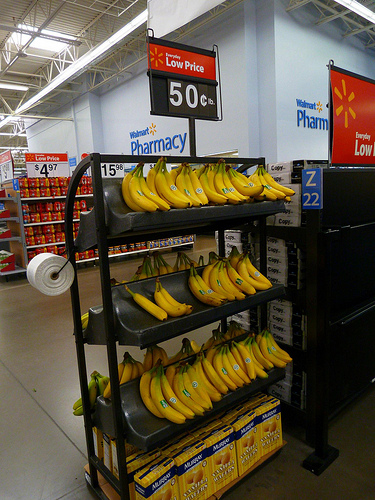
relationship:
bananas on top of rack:
[128, 165, 296, 438] [61, 146, 304, 500]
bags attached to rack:
[25, 251, 75, 296] [61, 146, 304, 500]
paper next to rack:
[214, 159, 329, 409] [61, 146, 304, 500]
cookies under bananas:
[96, 392, 285, 499] [128, 165, 296, 438]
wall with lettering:
[256, 0, 374, 162] [295, 99, 327, 131]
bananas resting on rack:
[128, 165, 296, 438] [61, 146, 304, 500]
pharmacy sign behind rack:
[128, 122, 188, 156] [61, 146, 304, 500]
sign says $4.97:
[25, 151, 70, 178] [34, 163, 58, 177]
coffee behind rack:
[17, 177, 98, 262] [61, 146, 304, 500]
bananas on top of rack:
[128, 165, 296, 438] [102, 176, 289, 451]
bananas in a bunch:
[128, 165, 296, 438] [122, 166, 171, 214]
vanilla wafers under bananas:
[91, 394, 284, 499] [128, 165, 296, 438]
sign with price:
[144, 31, 224, 123] [168, 82, 214, 109]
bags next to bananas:
[25, 251, 75, 296] [128, 165, 296, 438]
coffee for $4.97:
[17, 177, 98, 262] [34, 163, 58, 177]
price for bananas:
[168, 82, 214, 109] [128, 165, 296, 438]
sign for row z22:
[300, 169, 323, 211] [301, 165, 374, 435]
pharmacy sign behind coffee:
[128, 122, 188, 156] [17, 177, 98, 262]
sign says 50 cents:
[144, 31, 224, 123] [169, 80, 207, 109]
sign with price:
[25, 151, 70, 178] [34, 160, 57, 176]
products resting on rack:
[69, 147, 295, 499] [102, 176, 289, 451]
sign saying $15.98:
[91, 152, 125, 179] [102, 165, 125, 176]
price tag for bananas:
[165, 71, 218, 116] [128, 165, 296, 438]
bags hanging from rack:
[25, 251, 75, 296] [61, 146, 304, 500]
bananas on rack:
[128, 165, 296, 438] [61, 146, 304, 500]